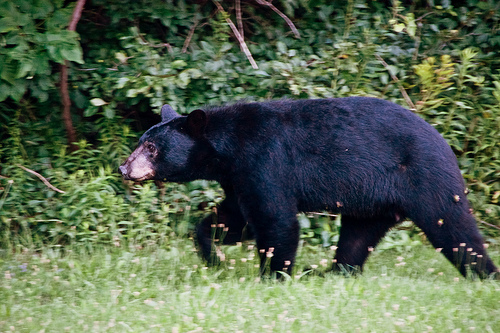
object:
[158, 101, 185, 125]
ear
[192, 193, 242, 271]
leg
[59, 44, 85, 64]
leaf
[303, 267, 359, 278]
paws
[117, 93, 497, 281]
bear